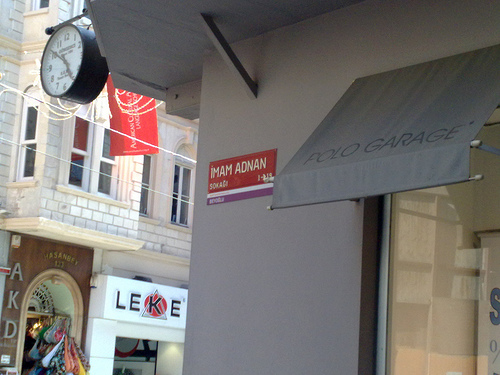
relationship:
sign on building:
[204, 148, 281, 206] [83, 1, 498, 373]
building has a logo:
[83, 1, 498, 373] [302, 122, 463, 171]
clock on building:
[38, 22, 109, 105] [83, 1, 498, 373]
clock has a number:
[38, 22, 109, 105] [62, 31, 70, 42]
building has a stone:
[2, 2, 197, 374] [70, 206, 81, 216]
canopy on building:
[267, 43, 500, 211] [83, 1, 498, 373]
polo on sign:
[304, 141, 360, 169] [267, 43, 500, 211]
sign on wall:
[204, 148, 281, 206] [183, 4, 402, 374]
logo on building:
[115, 284, 185, 320] [2, 2, 197, 374]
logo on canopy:
[302, 122, 463, 171] [267, 43, 500, 211]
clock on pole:
[38, 22, 109, 105] [44, 10, 95, 35]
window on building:
[374, 126, 499, 374] [83, 1, 498, 373]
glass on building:
[374, 126, 499, 374] [83, 1, 498, 373]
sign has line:
[204, 148, 281, 206] [206, 186, 275, 208]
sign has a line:
[204, 148, 281, 206] [205, 182, 282, 198]